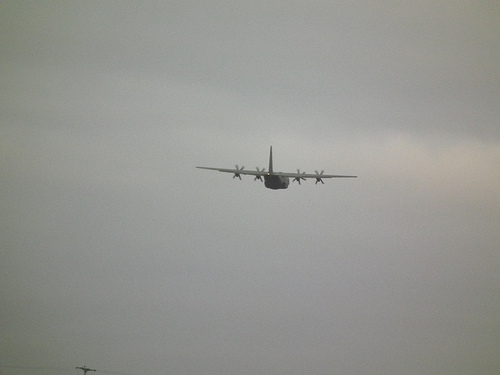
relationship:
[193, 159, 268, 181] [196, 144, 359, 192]
wing of aircraft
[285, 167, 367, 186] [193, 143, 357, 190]
right wing of plane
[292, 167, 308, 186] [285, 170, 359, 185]
propeller on right wing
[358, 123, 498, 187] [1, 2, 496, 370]
cloud in sky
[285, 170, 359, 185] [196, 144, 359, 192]
right wing on aircraft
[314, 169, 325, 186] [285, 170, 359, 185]
engine on right wing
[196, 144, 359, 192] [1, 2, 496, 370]
aircraft flying sky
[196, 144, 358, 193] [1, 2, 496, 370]
aircraft in sky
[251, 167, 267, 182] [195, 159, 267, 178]
propeller on wing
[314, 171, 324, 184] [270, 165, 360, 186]
engine on wing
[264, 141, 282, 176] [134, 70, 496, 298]
raised tail on plane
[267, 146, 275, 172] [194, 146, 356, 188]
raised tail of plane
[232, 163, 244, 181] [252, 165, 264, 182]
propeller on propeller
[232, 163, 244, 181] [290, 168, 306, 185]
propeller on propeller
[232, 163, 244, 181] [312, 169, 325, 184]
propeller on propeller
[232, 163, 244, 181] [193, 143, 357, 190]
propeller on plane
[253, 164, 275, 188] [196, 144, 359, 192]
light on back of aircraft